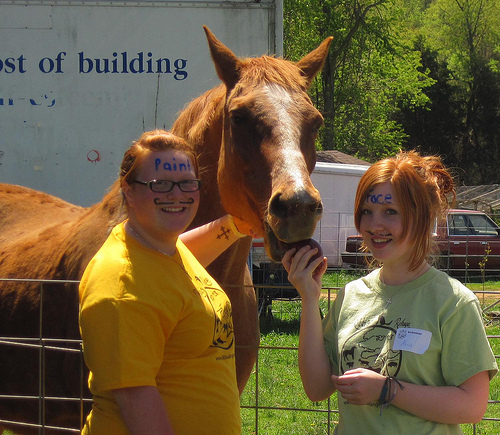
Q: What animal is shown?
A: A horse.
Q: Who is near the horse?
A: Two women.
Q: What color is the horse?
A: Brown.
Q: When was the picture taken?
A: Daytime.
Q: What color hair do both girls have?
A: Red.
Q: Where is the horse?
A: Behind a fence.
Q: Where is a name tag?
A: On the girl's shirt.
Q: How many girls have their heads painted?
A: 2.